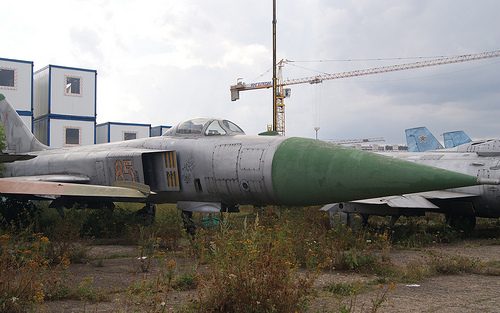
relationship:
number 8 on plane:
[108, 159, 125, 192] [1, 83, 499, 262]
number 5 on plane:
[121, 159, 136, 185] [1, 83, 499, 262]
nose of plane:
[272, 133, 499, 209] [1, 83, 499, 262]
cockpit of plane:
[165, 118, 246, 135] [1, 83, 499, 262]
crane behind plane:
[230, 0, 500, 134] [1, 83, 499, 262]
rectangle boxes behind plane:
[1, 57, 176, 148] [1, 83, 499, 262]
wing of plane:
[0, 165, 156, 210] [1, 83, 499, 262]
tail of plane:
[2, 94, 52, 153] [1, 83, 499, 262]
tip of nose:
[478, 178, 500, 185] [272, 133, 499, 209]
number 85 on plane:
[115, 159, 137, 183] [1, 83, 499, 262]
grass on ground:
[13, 198, 499, 246] [1, 198, 500, 313]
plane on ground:
[1, 83, 498, 240] [1, 198, 500, 313]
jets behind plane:
[324, 126, 499, 233] [1, 83, 499, 262]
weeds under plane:
[0, 204, 337, 312] [1, 83, 499, 262]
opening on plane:
[142, 152, 181, 193] [1, 83, 499, 262]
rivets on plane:
[212, 143, 265, 182] [1, 83, 499, 262]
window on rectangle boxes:
[64, 76, 81, 96] [1, 57, 176, 148]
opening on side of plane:
[142, 152, 181, 193] [1, 83, 499, 262]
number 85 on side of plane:
[115, 159, 137, 183] [1, 83, 499, 262]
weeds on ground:
[0, 204, 337, 312] [1, 198, 500, 313]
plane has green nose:
[1, 83, 499, 262] [272, 133, 499, 209]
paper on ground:
[404, 280, 422, 289] [1, 198, 500, 313]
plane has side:
[1, 83, 499, 262] [5, 145, 351, 206]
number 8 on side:
[108, 159, 125, 192] [5, 145, 351, 206]